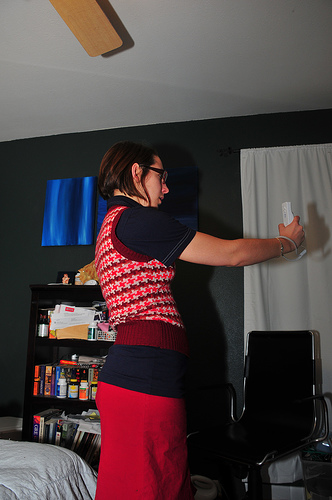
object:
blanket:
[28, 456, 68, 479]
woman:
[80, 140, 194, 499]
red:
[129, 408, 134, 413]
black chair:
[221, 330, 324, 472]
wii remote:
[262, 193, 300, 253]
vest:
[91, 212, 183, 328]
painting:
[40, 173, 114, 253]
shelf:
[34, 283, 44, 293]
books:
[36, 359, 54, 391]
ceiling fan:
[54, 10, 155, 66]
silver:
[307, 390, 331, 434]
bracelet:
[267, 236, 294, 270]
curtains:
[261, 179, 302, 187]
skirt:
[89, 365, 199, 481]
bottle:
[65, 377, 83, 409]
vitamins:
[75, 395, 77, 397]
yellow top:
[65, 372, 83, 383]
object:
[52, 321, 98, 346]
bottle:
[93, 335, 96, 343]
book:
[25, 416, 41, 439]